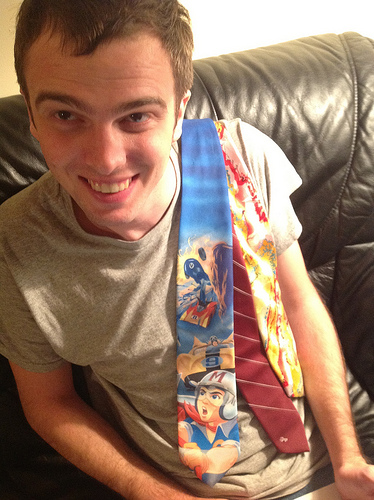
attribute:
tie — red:
[218, 240, 328, 437]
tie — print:
[214, 118, 304, 399]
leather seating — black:
[227, 40, 366, 123]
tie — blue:
[176, 118, 240, 486]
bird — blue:
[183, 255, 216, 301]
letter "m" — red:
[201, 355, 226, 402]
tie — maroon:
[232, 225, 310, 454]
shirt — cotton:
[0, 188, 285, 404]